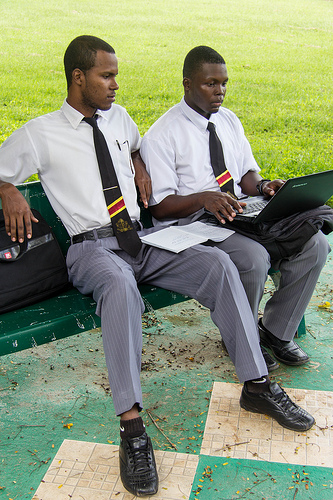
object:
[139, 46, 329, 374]
man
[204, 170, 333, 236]
laptop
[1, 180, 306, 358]
bench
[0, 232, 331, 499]
concrete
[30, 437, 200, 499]
square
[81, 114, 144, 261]
tie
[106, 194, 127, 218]
stripe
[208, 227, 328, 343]
pants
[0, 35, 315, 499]
man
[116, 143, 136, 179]
pocket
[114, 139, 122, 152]
pen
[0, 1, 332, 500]
field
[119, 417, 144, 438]
sock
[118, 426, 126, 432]
emblem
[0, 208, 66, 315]
bag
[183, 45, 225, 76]
hair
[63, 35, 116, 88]
hair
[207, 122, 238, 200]
tie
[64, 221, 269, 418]
pants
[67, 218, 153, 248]
belt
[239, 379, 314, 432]
shoes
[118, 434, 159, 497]
shoes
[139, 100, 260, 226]
shirt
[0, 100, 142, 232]
shirt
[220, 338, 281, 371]
shoe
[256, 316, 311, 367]
shoe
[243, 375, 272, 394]
sock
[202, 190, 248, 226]
hand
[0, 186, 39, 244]
hand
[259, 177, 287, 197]
hand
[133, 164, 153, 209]
hand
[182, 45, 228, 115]
head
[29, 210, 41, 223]
thumb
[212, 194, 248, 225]
finger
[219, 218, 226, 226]
fingernail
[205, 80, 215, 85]
eye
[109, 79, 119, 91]
nose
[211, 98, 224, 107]
mouth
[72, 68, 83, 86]
ear